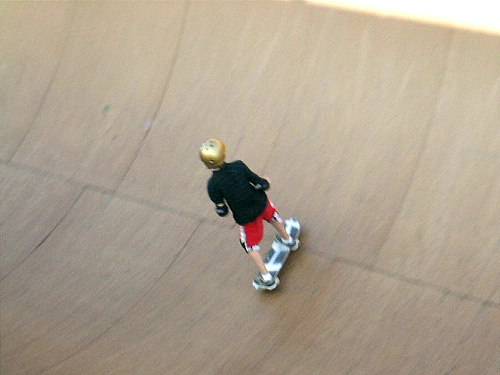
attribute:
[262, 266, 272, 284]
sock — white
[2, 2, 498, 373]
ramp — large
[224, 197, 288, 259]
shorts — red, white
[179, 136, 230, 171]
helmet — gold